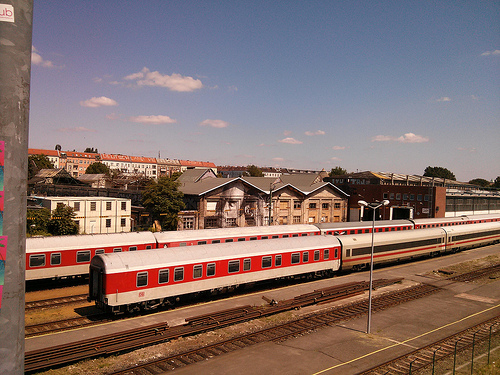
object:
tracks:
[26, 297, 92, 330]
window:
[106, 202, 111, 210]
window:
[106, 219, 111, 228]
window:
[121, 201, 127, 211]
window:
[121, 218, 125, 227]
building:
[31, 193, 131, 233]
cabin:
[89, 234, 340, 308]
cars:
[26, 230, 154, 282]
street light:
[359, 199, 389, 209]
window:
[293, 200, 302, 210]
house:
[303, 179, 360, 228]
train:
[25, 209, 498, 292]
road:
[112, 276, 497, 373]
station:
[20, 209, 495, 369]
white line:
[307, 300, 498, 372]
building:
[351, 169, 500, 219]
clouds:
[116, 65, 206, 92]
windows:
[291, 252, 301, 264]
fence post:
[450, 337, 464, 371]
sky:
[28, 0, 499, 181]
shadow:
[73, 301, 100, 319]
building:
[177, 172, 267, 228]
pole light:
[358, 198, 387, 335]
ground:
[90, 246, 500, 375]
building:
[30, 149, 145, 182]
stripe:
[116, 259, 340, 305]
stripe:
[343, 243, 444, 260]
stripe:
[447, 243, 499, 247]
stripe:
[23, 246, 88, 270]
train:
[88, 210, 499, 309]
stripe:
[323, 225, 413, 235]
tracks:
[25, 262, 498, 372]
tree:
[139, 172, 183, 232]